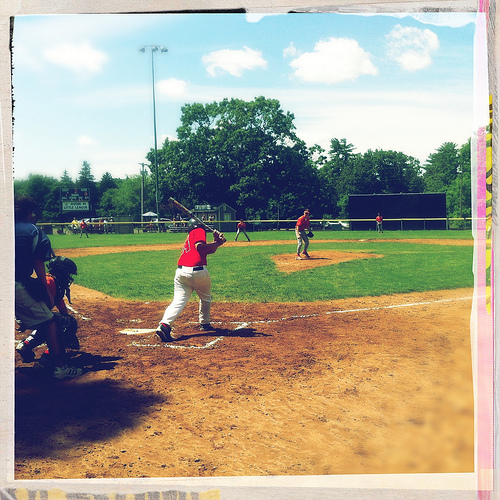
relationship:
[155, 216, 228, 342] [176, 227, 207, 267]
man wearing shirt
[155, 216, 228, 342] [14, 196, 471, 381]
man playing game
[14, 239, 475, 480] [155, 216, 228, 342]
dirt under man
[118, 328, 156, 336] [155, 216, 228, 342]
plate next to man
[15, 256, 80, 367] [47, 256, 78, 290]
catcher wearing mask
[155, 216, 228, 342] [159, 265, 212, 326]
man wearing pants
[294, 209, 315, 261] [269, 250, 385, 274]
pitcher standing on mound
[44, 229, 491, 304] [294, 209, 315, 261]
grass next to pitcher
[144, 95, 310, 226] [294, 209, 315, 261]
tree behind pitcher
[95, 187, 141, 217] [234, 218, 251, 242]
tree behind player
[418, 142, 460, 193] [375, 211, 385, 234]
tree behind player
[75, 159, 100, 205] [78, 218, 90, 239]
tree behind player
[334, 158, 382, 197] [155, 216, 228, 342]
tree behind player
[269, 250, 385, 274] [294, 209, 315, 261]
mound below pitcher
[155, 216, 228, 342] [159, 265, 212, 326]
man has pants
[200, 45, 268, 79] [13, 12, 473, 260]
cloud inside distance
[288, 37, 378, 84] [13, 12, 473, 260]
cloud inside distance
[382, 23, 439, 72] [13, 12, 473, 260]
cloud inside distance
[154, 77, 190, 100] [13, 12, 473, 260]
cloud inside distance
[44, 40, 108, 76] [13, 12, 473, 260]
cloud inside distance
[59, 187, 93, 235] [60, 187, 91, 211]
sign has information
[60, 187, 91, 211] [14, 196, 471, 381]
information for game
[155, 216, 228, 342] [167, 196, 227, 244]
man holding bat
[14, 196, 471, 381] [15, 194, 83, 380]
game has umpire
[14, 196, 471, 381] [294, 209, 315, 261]
game has pitcher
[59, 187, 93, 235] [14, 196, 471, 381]
sign at game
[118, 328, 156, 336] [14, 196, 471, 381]
plate at game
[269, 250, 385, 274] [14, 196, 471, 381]
mound at game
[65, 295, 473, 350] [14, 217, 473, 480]
path inside of field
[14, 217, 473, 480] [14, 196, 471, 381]
field for game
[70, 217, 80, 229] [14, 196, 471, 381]
person watching game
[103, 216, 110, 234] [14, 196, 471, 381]
person watching game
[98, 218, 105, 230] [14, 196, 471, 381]
person watching game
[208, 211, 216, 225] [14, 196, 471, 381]
person watching game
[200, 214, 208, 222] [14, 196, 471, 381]
person watching game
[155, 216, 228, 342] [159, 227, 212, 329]
man wearing uniform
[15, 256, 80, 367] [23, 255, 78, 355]
catcher wearing uniform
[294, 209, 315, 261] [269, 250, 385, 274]
pitcher on top of mound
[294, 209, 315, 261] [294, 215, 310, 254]
pitcher wearing uniform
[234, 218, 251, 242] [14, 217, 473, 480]
player playing on field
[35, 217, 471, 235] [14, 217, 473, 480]
fence around field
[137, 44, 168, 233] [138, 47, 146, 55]
pole has light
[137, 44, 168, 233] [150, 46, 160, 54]
pole has light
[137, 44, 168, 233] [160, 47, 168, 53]
pole has light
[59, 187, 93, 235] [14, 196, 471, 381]
sign for game